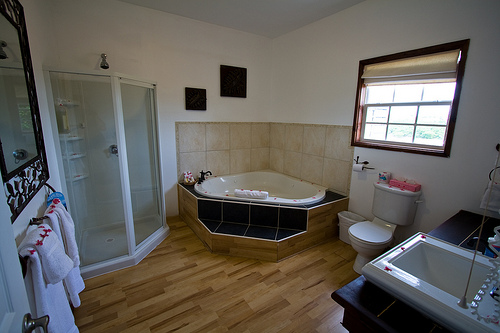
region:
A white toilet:
[345, 182, 420, 276]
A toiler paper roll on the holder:
[350, 160, 365, 170]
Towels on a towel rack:
[18, 192, 94, 332]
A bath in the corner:
[183, 167, 328, 233]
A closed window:
[352, 60, 448, 152]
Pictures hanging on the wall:
[184, 64, 248, 112]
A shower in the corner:
[43, 61, 175, 263]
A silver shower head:
[100, 52, 110, 68]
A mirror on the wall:
[0, 17, 44, 171]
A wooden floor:
[75, 213, 362, 330]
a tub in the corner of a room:
[180, 134, 350, 279]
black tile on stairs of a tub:
[210, 193, 295, 243]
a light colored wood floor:
[189, 277, 289, 322]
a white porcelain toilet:
[350, 180, 417, 264]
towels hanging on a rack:
[12, 188, 92, 303]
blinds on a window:
[358, 55, 460, 80]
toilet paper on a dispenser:
[352, 158, 371, 175]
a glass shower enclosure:
[52, 73, 162, 260]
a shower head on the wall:
[93, 50, 110, 70]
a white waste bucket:
[335, 209, 366, 241]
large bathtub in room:
[200, 155, 325, 214]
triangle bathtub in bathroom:
[207, 143, 324, 208]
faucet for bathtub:
[194, 160, 219, 182]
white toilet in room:
[337, 170, 422, 256]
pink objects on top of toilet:
[395, 176, 426, 195]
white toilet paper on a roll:
[350, 163, 366, 175]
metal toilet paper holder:
[360, 159, 372, 176]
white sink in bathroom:
[356, 240, 499, 321]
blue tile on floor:
[205, 205, 300, 232]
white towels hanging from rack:
[21, 187, 100, 299]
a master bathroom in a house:
[10, 4, 499, 322]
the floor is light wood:
[64, 217, 388, 331]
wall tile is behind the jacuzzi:
[171, 115, 352, 227]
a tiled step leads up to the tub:
[193, 208, 306, 265]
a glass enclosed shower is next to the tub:
[41, 60, 169, 280]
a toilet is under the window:
[345, 178, 421, 275]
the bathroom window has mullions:
[365, 87, 441, 148]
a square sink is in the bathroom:
[357, 225, 499, 323]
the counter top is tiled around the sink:
[331, 203, 495, 326]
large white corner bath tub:
[193, 168, 326, 204]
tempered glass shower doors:
[45, 65, 170, 280]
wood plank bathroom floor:
[124, 270, 311, 328]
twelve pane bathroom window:
[351, 37, 469, 156]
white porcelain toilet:
[348, 180, 418, 274]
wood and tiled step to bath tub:
[194, 195, 310, 264]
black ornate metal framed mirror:
[0, 0, 52, 225]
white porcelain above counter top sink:
[360, 229, 498, 331]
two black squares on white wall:
[181, 62, 248, 112]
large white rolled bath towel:
[231, 187, 270, 199]